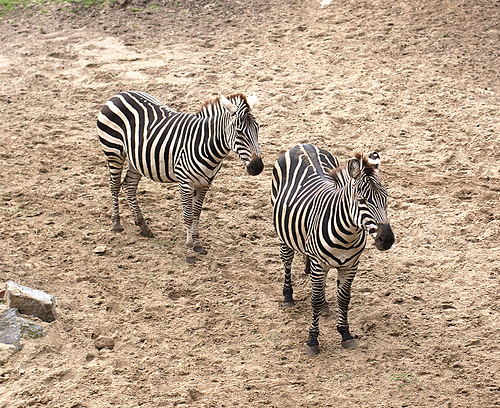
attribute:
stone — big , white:
[1, 277, 58, 362]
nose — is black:
[372, 222, 394, 251]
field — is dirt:
[0, 4, 500, 406]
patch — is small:
[86, 0, 146, 26]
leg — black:
[306, 260, 330, 352]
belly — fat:
[265, 178, 315, 248]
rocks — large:
[1, 282, 60, 367]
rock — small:
[0, 279, 57, 327]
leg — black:
[300, 263, 325, 360]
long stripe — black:
[300, 145, 331, 185]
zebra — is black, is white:
[270, 137, 397, 351]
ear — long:
[213, 86, 241, 114]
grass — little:
[312, 33, 417, 148]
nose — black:
[246, 152, 267, 176]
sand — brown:
[128, 276, 268, 386]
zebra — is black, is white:
[94, 86, 266, 267]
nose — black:
[371, 223, 395, 253]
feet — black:
[291, 325, 371, 354]